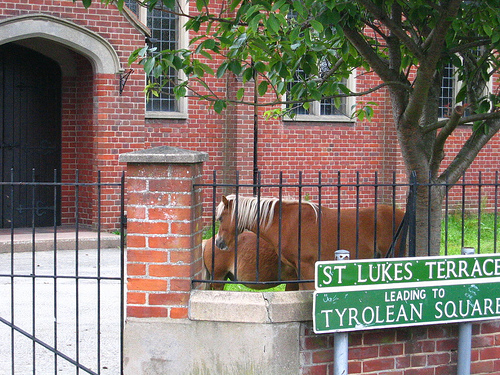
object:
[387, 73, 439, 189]
frisbee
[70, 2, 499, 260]
tree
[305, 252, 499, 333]
sign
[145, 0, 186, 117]
window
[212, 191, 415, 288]
horse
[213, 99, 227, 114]
leaf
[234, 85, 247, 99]
leaf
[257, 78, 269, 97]
leaf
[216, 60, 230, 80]
leaf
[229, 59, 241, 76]
leaf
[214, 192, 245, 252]
head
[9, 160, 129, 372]
gates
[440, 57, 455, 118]
window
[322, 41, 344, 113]
window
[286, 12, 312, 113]
window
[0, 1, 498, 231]
building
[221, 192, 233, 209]
ear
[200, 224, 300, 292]
horses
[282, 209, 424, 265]
body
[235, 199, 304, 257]
neck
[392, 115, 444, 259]
bark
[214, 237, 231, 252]
mouth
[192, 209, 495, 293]
lawn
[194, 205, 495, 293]
yard